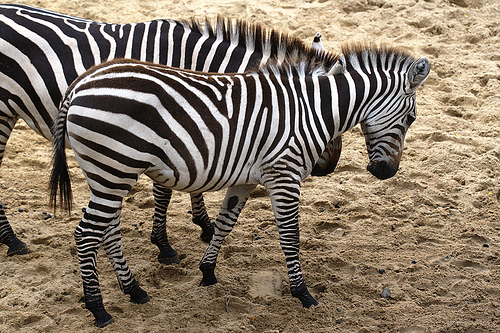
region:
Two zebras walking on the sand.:
[1, 1, 431, 321]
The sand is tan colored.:
[432, 5, 492, 325]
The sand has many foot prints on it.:
[431, 5, 496, 327]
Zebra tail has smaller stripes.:
[42, 90, 72, 143]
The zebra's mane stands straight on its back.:
[192, 10, 314, 50]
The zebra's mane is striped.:
[206, 11, 333, 51]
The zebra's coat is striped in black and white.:
[47, 55, 437, 326]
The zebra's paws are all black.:
[77, 265, 322, 325]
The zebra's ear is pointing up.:
[405, 51, 432, 86]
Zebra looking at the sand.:
[360, 41, 430, 183]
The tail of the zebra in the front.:
[43, 95, 70, 197]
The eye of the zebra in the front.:
[397, 107, 417, 131]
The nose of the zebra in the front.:
[370, 160, 395, 182]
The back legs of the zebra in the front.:
[76, 180, 146, 315]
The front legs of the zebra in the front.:
[200, 183, 314, 306]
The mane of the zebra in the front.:
[292, 29, 413, 78]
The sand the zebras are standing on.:
[2, 128, 492, 331]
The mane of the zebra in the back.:
[187, 8, 344, 70]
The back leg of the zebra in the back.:
[0, 108, 29, 258]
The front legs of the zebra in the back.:
[155, 176, 215, 256]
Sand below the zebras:
[0, 1, 499, 328]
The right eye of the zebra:
[407, 104, 417, 126]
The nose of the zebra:
[370, 163, 397, 180]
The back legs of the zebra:
[66, 190, 153, 324]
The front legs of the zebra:
[199, 183, 325, 304]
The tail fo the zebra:
[48, 102, 76, 208]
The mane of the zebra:
[338, 45, 414, 72]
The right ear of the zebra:
[408, 52, 428, 84]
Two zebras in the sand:
[1, 7, 431, 322]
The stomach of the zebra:
[148, 165, 235, 191]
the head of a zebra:
[353, 41, 440, 187]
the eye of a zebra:
[400, 110, 420, 128]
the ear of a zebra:
[404, 53, 436, 90]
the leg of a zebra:
[262, 174, 316, 287]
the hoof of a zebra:
[123, 282, 154, 307]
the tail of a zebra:
[41, 73, 80, 218]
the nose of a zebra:
[376, 158, 404, 182]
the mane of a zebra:
[331, 33, 419, 78]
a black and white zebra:
[36, 37, 439, 332]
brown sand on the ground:
[2, 0, 498, 332]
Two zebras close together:
[8, 5, 447, 317]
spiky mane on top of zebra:
[252, 36, 432, 86]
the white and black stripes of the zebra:
[70, 45, 390, 315]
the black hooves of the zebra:
[75, 288, 115, 329]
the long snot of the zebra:
[357, 55, 417, 205]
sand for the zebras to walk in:
[322, 205, 492, 330]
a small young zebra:
[40, 43, 440, 329]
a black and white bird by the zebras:
[312, 27, 325, 55]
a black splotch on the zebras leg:
[223, 192, 243, 223]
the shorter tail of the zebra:
[36, 68, 83, 225]